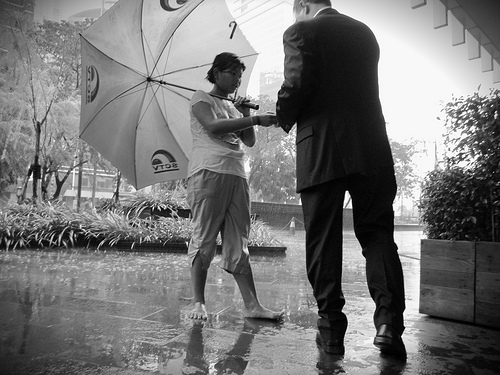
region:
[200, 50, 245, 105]
head of a person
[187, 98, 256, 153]
arm of a person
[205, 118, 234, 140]
elbow of a person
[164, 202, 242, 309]
leg of a person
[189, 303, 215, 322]
feet of a person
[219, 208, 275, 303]
leg of a person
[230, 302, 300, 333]
feet of a person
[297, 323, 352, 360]
feet of a person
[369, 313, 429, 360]
feet of a person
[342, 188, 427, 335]
leg of a person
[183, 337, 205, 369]
reflection on the ground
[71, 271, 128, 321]
the ground is wet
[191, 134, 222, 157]
women is wearing a white shirt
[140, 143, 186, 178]
logo on the umbrella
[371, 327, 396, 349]
a black shoe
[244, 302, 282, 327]
the womens foot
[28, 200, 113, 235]
a plant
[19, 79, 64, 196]
a tree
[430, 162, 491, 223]
a green plant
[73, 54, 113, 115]
small design on bottom of umbrella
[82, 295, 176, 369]
water standing on concrete path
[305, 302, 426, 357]
pair of black dress shoes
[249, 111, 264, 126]
wristwatch on arm of woman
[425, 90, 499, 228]
small bush covered in leaves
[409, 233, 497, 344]
large grey stone planter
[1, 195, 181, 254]
row of plants covered in leaves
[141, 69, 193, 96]
metal umbrella pole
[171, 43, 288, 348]
woman holding umbrella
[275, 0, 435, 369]
man in dark business suit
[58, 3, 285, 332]
person is holding an umbrella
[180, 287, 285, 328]
person not wearing any shoes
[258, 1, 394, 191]
man is wearing suit jacket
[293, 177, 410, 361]
man is wearing slacks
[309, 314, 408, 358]
man's shoes are black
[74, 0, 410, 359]
man is giving something to person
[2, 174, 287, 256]
plants on the ground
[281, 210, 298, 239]
plastic cone on the ground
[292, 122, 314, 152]
pocket on man's jacket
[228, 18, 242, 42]
black strap on the umbrella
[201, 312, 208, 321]
white colored human toe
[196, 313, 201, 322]
white colored human toe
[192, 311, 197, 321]
white colored human toe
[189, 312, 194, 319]
white colored human toe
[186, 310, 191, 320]
white colored human toe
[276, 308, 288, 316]
white colored human toe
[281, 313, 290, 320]
white colored human toe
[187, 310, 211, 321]
white colored human toes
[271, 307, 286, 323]
white colored human toe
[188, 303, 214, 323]
white colored human foot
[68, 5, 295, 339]
woman holding a umbrella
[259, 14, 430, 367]
a man in a suit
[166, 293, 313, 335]
a woman without shoes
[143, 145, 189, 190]
decal on the umbrella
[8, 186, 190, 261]
plants in the background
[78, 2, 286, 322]
Bare foot girl with an umbrella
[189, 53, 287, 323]
Girl bare foot on the pavement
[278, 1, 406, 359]
Guy in a dark colored suit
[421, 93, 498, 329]
Plants in a wooden planter box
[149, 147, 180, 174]
Corporate logo design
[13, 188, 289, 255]
Multi level planter box